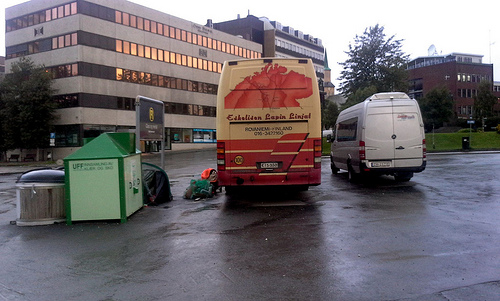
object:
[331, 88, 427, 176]
van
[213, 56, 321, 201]
bus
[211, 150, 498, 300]
parking lot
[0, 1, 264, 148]
building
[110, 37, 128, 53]
windows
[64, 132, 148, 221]
trash bin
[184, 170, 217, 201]
bags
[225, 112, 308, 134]
writing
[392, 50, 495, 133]
building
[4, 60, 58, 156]
tree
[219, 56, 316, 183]
back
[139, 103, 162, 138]
sign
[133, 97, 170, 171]
poles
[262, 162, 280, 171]
license plate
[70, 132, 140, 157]
top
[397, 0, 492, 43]
clouds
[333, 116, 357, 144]
windows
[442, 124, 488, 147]
grass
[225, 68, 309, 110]
design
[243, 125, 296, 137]
text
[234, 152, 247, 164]
circle label